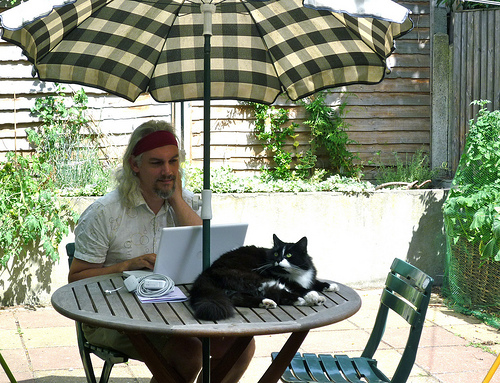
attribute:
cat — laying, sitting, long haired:
[187, 232, 339, 319]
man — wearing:
[119, 130, 189, 227]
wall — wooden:
[2, 0, 429, 179]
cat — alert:
[200, 233, 334, 343]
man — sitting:
[67, 119, 199, 286]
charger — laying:
[130, 266, 168, 303]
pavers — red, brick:
[4, 286, 499, 378]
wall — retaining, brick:
[322, 198, 439, 259]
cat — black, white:
[185, 222, 342, 324]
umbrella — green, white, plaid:
[6, 0, 410, 102]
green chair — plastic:
[270, 347, 394, 381]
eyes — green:
[271, 252, 296, 257]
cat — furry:
[185, 226, 330, 326]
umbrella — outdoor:
[0, 1, 410, 359]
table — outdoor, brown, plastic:
[33, 261, 371, 378]